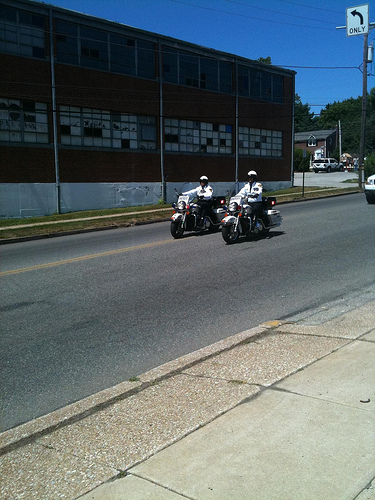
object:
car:
[312, 158, 344, 173]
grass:
[268, 184, 304, 191]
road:
[6, 205, 368, 414]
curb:
[5, 178, 361, 250]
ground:
[291, 193, 372, 271]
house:
[295, 128, 338, 168]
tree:
[343, 115, 372, 159]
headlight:
[178, 201, 186, 210]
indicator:
[238, 205, 242, 209]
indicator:
[185, 205, 190, 208]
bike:
[221, 196, 282, 244]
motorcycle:
[170, 195, 227, 238]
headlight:
[228, 201, 238, 211]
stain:
[0, 297, 47, 312]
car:
[363, 171, 375, 202]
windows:
[80, 21, 111, 72]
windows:
[261, 130, 271, 156]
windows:
[164, 118, 178, 152]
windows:
[24, 102, 49, 142]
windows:
[201, 123, 219, 153]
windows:
[136, 116, 156, 150]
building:
[0, 0, 297, 223]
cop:
[236, 171, 263, 233]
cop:
[180, 176, 212, 227]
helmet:
[248, 171, 257, 180]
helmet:
[200, 176, 208, 185]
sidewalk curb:
[0, 318, 288, 500]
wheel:
[170, 219, 184, 238]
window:
[60, 108, 81, 146]